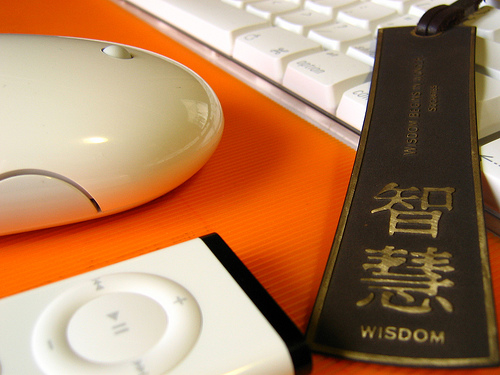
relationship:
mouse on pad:
[0, 33, 225, 236] [0, 0, 499, 374]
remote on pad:
[4, 231, 312, 374] [0, 0, 499, 374]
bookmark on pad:
[303, 27, 498, 370] [0, 0, 499, 374]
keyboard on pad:
[115, 1, 500, 239] [0, 0, 499, 374]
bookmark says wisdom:
[303, 27, 498, 370] [363, 324, 445, 346]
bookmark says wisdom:
[303, 27, 498, 370] [402, 121, 417, 154]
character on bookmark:
[357, 182, 455, 313] [303, 27, 498, 370]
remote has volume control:
[4, 231, 312, 374] [30, 294, 184, 352]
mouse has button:
[0, 33, 225, 236] [2, 173, 100, 238]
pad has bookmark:
[0, 0, 499, 374] [303, 27, 498, 370]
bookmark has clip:
[303, 27, 498, 370] [416, 0, 482, 34]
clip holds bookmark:
[416, 0, 482, 34] [303, 27, 498, 370]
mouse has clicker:
[0, 33, 225, 236] [103, 44, 130, 59]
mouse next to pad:
[0, 33, 225, 236] [0, 0, 499, 374]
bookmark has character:
[303, 27, 498, 370] [357, 182, 455, 313]